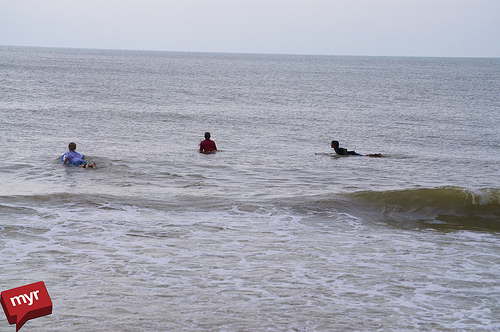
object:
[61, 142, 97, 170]
boy water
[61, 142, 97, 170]
boy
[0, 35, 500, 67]
skyline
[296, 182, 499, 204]
crest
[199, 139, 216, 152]
clothing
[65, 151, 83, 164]
clothes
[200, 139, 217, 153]
red shirt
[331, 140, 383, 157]
boy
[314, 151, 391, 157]
surfboard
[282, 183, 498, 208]
wave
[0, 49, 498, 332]
ocean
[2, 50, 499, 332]
water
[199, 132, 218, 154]
boy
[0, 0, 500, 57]
sky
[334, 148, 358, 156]
clothing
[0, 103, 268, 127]
waves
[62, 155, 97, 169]
surfboard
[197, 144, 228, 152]
surfboard